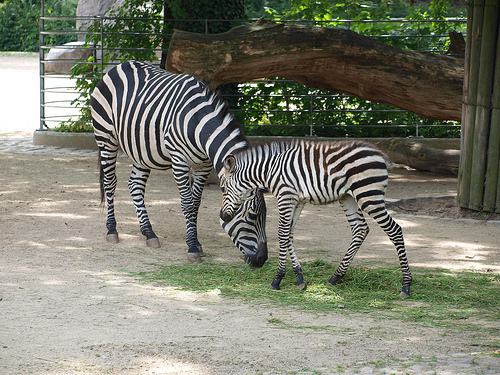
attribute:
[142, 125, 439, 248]
strips — black and white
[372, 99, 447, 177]
leaves — green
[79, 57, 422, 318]
zebras — black and white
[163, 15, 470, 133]
large wooden branch — large and wooden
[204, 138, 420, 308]
very young zebra — very young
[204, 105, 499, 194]
large log —  large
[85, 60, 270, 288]
zebra is black — white